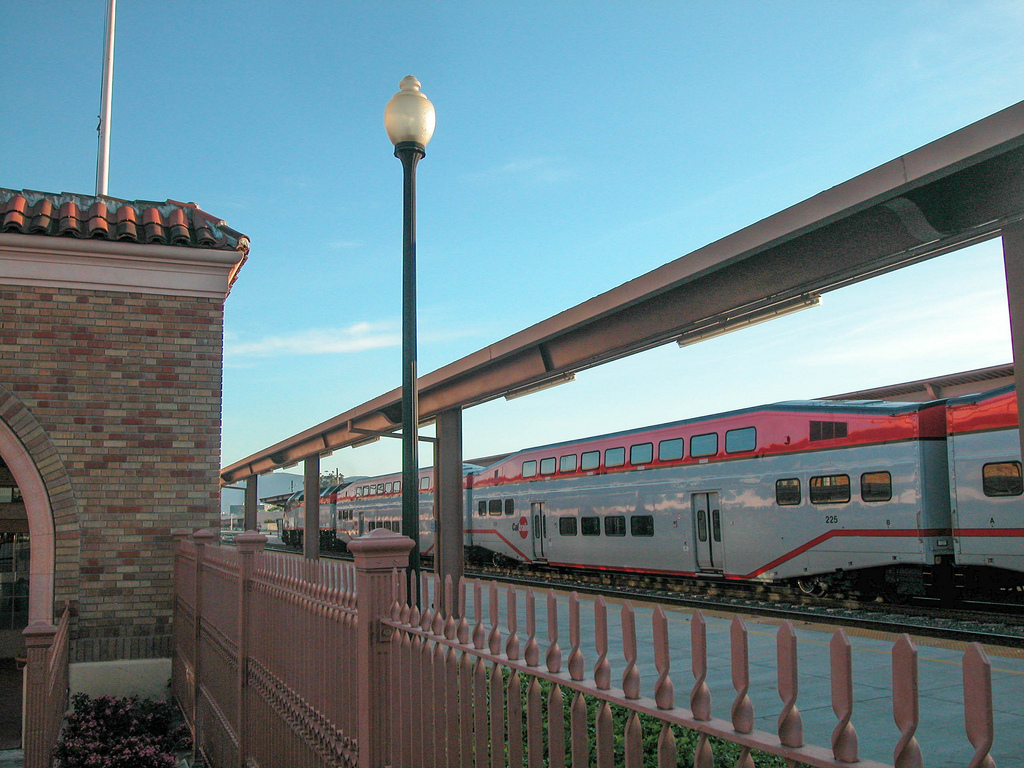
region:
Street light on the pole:
[381, 70, 446, 150]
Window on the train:
[714, 421, 765, 456]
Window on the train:
[853, 468, 891, 503]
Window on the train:
[972, 451, 1023, 503]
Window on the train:
[626, 511, 655, 535]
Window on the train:
[556, 511, 576, 532]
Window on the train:
[514, 454, 535, 486]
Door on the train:
[686, 489, 719, 573]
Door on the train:
[525, 495, 555, 571]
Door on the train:
[353, 502, 372, 545]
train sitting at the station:
[264, 348, 1020, 609]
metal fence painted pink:
[150, 522, 1005, 760]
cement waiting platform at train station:
[210, 533, 1013, 759]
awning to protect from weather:
[229, 110, 1008, 525]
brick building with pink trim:
[10, 176, 252, 726]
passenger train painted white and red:
[269, 361, 1010, 611]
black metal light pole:
[378, 108, 437, 624]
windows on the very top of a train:
[510, 399, 786, 485]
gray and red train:
[263, 398, 1017, 586]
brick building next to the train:
[12, 183, 232, 708]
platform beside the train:
[208, 545, 943, 765]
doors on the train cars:
[519, 497, 723, 574]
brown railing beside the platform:
[170, 522, 996, 766]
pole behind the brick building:
[88, 10, 150, 185]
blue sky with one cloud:
[10, 7, 1020, 485]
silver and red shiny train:
[275, 357, 1022, 585]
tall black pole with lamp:
[385, 70, 439, 606]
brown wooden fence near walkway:
[158, 516, 1013, 766]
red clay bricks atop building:
[3, 193, 222, 248]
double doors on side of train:
[685, 484, 728, 584]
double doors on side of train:
[528, 495, 547, 565]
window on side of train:
[628, 512, 663, 536]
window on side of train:
[601, 509, 628, 539]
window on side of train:
[577, 505, 606, 545]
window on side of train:
[553, 514, 582, 541]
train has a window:
[578, 450, 604, 471]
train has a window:
[656, 434, 683, 461]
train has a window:
[726, 425, 761, 452]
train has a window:
[858, 470, 888, 500]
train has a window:
[776, 476, 797, 505]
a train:
[555, 405, 960, 618]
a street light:
[370, 60, 437, 160]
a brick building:
[108, 355, 176, 469]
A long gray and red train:
[269, 359, 1019, 619]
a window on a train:
[977, 456, 1016, 505]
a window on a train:
[856, 454, 895, 508]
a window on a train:
[804, 473, 846, 499]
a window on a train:
[769, 472, 801, 512]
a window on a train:
[624, 520, 662, 541]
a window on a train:
[570, 507, 609, 546]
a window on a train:
[544, 501, 592, 537]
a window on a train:
[490, 492, 517, 512]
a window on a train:
[480, 494, 504, 520]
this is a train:
[449, 439, 1009, 614]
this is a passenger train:
[469, 330, 942, 621]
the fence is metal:
[264, 491, 565, 757]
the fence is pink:
[155, 512, 538, 722]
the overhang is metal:
[370, 241, 792, 442]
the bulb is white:
[400, 39, 459, 157]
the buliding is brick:
[8, 208, 277, 693]